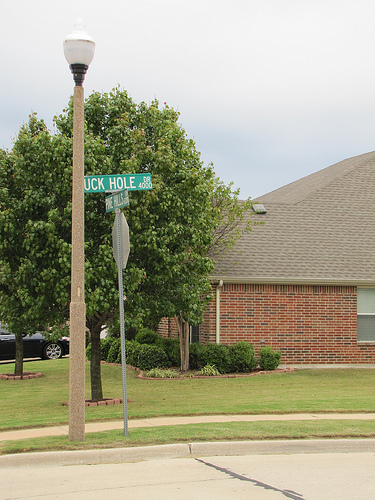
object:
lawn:
[0, 354, 374, 452]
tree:
[1, 81, 267, 404]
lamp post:
[63, 14, 97, 444]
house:
[153, 150, 375, 368]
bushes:
[258, 341, 280, 372]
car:
[0, 325, 71, 360]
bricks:
[0, 370, 42, 380]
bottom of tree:
[12, 334, 26, 375]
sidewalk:
[0, 410, 374, 441]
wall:
[156, 285, 375, 367]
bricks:
[157, 283, 375, 367]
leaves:
[158, 173, 191, 221]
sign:
[83, 173, 153, 194]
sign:
[104, 188, 131, 213]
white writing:
[104, 190, 129, 210]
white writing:
[84, 176, 152, 191]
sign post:
[115, 208, 131, 438]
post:
[68, 84, 88, 444]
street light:
[63, 14, 97, 85]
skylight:
[251, 202, 267, 216]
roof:
[181, 149, 375, 283]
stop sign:
[111, 209, 130, 269]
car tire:
[44, 341, 64, 360]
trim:
[356, 287, 374, 342]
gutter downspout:
[215, 280, 225, 346]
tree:
[173, 158, 266, 373]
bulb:
[63, 26, 98, 65]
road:
[1, 444, 374, 498]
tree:
[0, 107, 59, 377]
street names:
[84, 172, 154, 193]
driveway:
[0, 348, 78, 363]